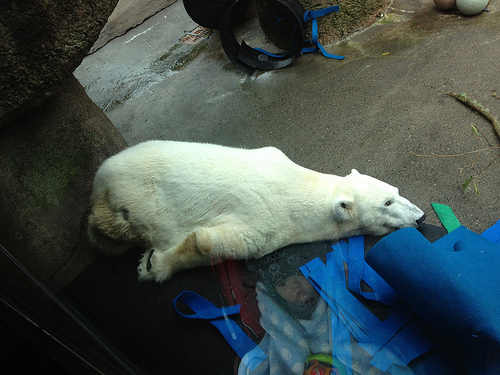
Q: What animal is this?
A: A bear.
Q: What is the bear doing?
A: Crawling on the floor.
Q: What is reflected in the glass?
A: A baby.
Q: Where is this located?
A: A zoo.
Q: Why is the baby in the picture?
A: Its image is reflecting in glass.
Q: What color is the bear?
A: White.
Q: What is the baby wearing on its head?
A: A hat.